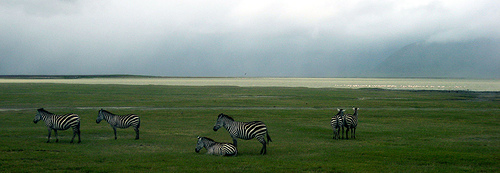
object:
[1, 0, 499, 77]
sky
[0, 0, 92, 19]
clouds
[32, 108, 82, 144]
zebra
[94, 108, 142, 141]
zebra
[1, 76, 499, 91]
water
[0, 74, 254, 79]
land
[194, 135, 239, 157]
zebra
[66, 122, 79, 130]
stripes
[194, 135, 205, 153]
head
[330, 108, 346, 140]
zebra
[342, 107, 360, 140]
zebra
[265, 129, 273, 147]
tail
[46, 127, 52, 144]
leg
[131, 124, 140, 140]
leg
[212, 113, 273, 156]
standing zebra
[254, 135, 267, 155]
leg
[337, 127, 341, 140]
leg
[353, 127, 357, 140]
leg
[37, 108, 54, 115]
hair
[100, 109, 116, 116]
hair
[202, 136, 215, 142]
hair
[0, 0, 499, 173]
photo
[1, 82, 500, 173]
grassy area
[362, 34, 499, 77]
hills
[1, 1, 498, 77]
background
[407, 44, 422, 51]
trees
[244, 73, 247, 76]
birds